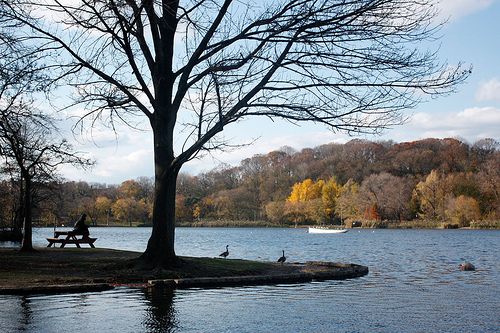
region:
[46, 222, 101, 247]
A picnic table by the water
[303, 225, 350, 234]
A white boat in the water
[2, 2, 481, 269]
A large tree in the foreground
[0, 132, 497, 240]
A forest in the background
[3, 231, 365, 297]
A very small peninsula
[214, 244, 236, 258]
A goose on land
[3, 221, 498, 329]
A body of water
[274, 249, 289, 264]
A goose under the tree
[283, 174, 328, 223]
A very yellow tree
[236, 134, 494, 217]
A hill with trees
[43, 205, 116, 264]
person sitting by the river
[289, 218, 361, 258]
a small white boat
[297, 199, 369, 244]
a small white boat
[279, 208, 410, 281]
a small white boat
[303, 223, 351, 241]
A white boat on a lake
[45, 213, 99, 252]
A guy sitting on a bench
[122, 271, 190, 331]
Reflection of tree in the water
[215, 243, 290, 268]
Birds walking near a lake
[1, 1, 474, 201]
A large tree with no leaves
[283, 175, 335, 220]
A tree with yellow leaves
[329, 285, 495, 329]
Ripples on lake water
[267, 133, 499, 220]
A large patch a trees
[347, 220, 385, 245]
Birds floating on a lake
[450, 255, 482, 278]
An object floating in a lake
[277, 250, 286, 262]
goose standing on shore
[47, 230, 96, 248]
wooden picnic table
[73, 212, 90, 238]
person sitting on the picnic table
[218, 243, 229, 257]
goose standing on the shore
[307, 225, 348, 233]
small white boat in the water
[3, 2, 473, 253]
large tree with no leaves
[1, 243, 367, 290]
small piece of land surrounded by water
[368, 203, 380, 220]
red tree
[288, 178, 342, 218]
trees with yellow leaves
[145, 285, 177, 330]
shadow of the tree in the water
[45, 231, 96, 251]
a wooden picnic table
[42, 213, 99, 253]
a person sitting on a picnic table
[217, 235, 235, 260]
a goose on the lake's shore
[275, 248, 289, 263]
a goose on the shore of the lake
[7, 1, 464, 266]
a tree growing on the shore of the lake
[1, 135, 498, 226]
the fall-colored trees in the distance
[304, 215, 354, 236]
a white boat on the water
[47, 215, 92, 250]
a woman sitting on a picnic table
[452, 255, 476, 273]
a goose in the water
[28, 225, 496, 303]
the blue water of a lake